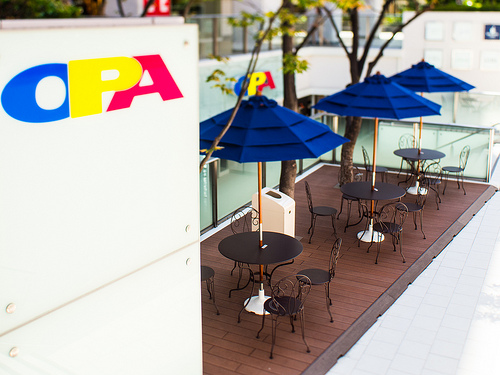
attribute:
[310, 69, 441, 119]
umbrella — blue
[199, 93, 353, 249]
umbrella — blue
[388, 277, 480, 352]
tile — white 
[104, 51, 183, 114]
letter — red 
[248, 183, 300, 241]
white metal — trash receptacle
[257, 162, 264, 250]
parasol handle — brown wooden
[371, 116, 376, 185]
parasol handle — brown wooden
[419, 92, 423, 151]
parasol handle — brown wooden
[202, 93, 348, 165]
parasol — brown wooden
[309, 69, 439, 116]
parasol — brown wooden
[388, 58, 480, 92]
parasol — brown wooden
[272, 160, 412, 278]
wire chair — brown 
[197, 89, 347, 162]
umbrella — blue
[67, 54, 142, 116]
letter "p" — yellow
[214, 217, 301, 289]
table — small, brown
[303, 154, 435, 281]
patio table — black 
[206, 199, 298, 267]
table — black 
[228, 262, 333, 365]
patio chair — black 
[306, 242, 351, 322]
chair — black 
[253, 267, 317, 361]
chair — black patio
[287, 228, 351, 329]
chair — black patio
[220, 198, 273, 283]
chair — black patio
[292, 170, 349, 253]
chair — black patio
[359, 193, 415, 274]
chair — black patio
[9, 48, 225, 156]
logo — colorized